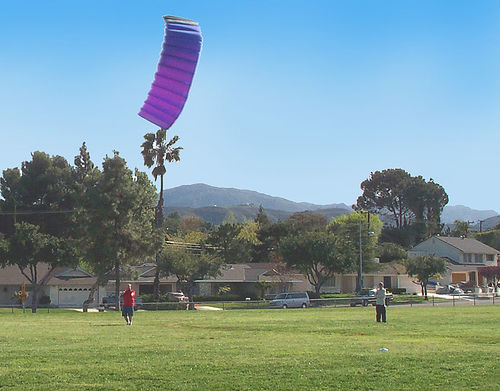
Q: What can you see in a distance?
A: Mountain.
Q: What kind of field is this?
A: Green grassy.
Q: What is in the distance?
A: Trees.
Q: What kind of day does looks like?
A: Clear blue sky.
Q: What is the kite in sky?
A: Purple kite.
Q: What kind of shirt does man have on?
A: Red shirt.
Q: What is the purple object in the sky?
A: Kite.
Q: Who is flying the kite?
A: Person in red shirt.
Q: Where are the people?
A: Park.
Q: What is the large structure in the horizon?
A: Mountain.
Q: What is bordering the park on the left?
A: Trees.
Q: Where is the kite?
A: Sky.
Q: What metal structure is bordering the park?
A: Metal fence.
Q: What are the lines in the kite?
A: Ridges.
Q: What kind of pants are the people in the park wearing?
A: Shorts and pants.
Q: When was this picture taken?
A: During the day.